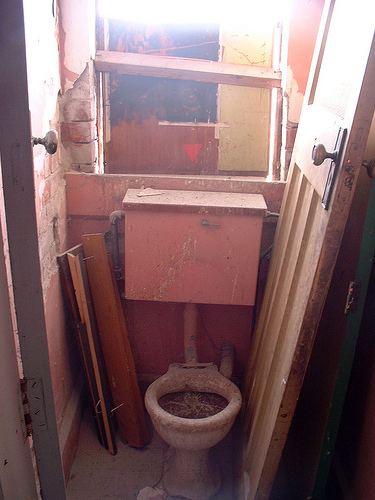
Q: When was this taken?
A: Daytime.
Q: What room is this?
A: Bathroom.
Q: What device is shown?
A: Toilet.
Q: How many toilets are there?
A: One.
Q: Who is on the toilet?
A: No one.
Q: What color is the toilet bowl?
A: White.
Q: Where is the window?
A: Above the toilet.